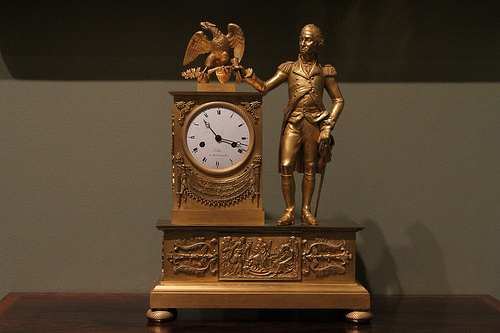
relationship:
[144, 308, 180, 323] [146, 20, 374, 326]
foot pad holding up clock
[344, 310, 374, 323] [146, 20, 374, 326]
foot pad holding up clock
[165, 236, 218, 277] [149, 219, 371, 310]
design etched on base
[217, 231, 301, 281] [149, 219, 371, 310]
design etched on base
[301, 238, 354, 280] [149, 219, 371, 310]
design etched on base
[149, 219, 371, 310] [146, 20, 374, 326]
base of clock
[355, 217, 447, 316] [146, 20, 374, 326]
shadow of clock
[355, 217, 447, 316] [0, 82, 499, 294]
shadow on wall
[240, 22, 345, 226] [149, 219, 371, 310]
image standing on base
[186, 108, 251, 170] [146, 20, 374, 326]
face of clock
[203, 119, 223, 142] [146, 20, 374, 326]
hand on clock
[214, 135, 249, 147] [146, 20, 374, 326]
hand on clock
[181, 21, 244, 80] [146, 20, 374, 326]
eagle perched on top of clock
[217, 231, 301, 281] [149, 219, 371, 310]
design on base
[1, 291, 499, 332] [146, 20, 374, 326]
table under clock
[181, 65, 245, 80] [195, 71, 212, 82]
branch in claws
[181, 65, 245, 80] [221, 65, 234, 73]
branch in claws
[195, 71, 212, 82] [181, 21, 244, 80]
claws of eagle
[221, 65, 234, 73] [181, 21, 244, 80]
claws of eagle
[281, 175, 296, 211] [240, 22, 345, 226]
sock on image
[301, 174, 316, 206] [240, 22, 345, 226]
sock on image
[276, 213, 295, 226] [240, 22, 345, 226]
shoe on image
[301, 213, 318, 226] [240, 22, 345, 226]
shoe on image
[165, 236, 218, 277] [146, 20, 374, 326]
design around clock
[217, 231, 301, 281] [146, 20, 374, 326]
design around clock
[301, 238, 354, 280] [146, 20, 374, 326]
design around clock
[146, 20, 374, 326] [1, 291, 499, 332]
clock on table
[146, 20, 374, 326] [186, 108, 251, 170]
clock with face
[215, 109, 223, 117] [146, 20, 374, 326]
roman numeral on clock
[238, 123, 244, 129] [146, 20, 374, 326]
roman numeral on clock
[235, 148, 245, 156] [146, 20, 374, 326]
roman numeral on clock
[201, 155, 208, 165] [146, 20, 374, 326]
roman numeral on clock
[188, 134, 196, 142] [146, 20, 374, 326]
roman numeral on clock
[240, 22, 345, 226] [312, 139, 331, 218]
image holding sword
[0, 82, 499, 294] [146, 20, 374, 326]
wall behind clock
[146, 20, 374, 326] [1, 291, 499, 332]
clock on top of table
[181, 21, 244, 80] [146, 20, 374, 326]
eagle on top of clock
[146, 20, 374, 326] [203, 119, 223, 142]
clock has hand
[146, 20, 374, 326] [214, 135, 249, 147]
clock has hand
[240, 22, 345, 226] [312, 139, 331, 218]
image has sword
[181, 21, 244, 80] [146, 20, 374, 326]
eagle above clock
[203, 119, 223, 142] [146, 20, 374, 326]
hand of clock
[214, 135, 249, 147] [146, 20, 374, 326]
hand of clock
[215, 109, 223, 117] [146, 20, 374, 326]
roman numeral on face of clock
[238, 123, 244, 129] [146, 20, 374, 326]
roman numeral on face of clock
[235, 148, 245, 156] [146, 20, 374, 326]
roman numeral on face of clock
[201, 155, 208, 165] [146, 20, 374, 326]
roman numeral on face of clock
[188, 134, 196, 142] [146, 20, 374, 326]
roman numeral on face of clock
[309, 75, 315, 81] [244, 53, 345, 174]
button on jacket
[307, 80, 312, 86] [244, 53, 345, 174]
button on jacket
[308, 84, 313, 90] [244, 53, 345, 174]
button on jacket